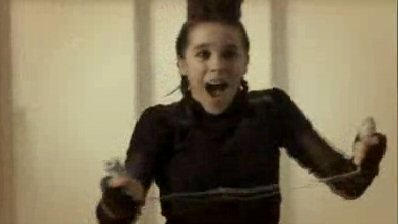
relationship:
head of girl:
[169, 0, 258, 114] [94, 0, 385, 221]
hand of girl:
[350, 128, 385, 163] [94, 0, 385, 221]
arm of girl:
[94, 100, 162, 222] [94, 0, 385, 221]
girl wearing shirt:
[94, 0, 385, 221] [96, 85, 378, 220]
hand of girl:
[102, 168, 158, 203] [94, 28, 386, 221]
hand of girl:
[350, 128, 385, 163] [94, 28, 386, 221]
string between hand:
[102, 118, 376, 193] [102, 168, 158, 203]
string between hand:
[102, 118, 376, 193] [350, 128, 385, 163]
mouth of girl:
[200, 71, 231, 96] [94, 0, 385, 221]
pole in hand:
[100, 156, 127, 177] [102, 168, 158, 203]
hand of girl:
[102, 168, 158, 203] [94, 0, 385, 221]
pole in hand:
[350, 114, 381, 171] [350, 128, 385, 163]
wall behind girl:
[9, 11, 392, 216] [94, 0, 385, 221]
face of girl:
[175, 20, 250, 115] [94, 0, 385, 221]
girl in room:
[94, 0, 385, 221] [2, 1, 395, 221]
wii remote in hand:
[104, 115, 375, 201] [350, 128, 385, 163]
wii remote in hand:
[104, 115, 375, 201] [102, 168, 158, 203]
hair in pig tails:
[173, 1, 254, 116] [155, 47, 277, 128]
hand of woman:
[102, 168, 158, 203] [94, 2, 385, 220]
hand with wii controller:
[102, 168, 158, 203] [98, 115, 375, 206]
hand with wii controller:
[350, 128, 385, 163] [98, 115, 375, 206]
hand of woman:
[350, 128, 385, 163] [94, 2, 385, 220]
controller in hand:
[352, 119, 382, 183] [351, 131, 385, 170]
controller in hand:
[102, 158, 128, 176] [100, 171, 144, 207]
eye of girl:
[197, 47, 210, 59] [94, 0, 385, 221]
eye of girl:
[224, 49, 236, 57] [94, 0, 385, 221]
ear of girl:
[174, 55, 189, 76] [103, 14, 394, 216]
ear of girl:
[244, 49, 249, 73] [103, 14, 394, 216]